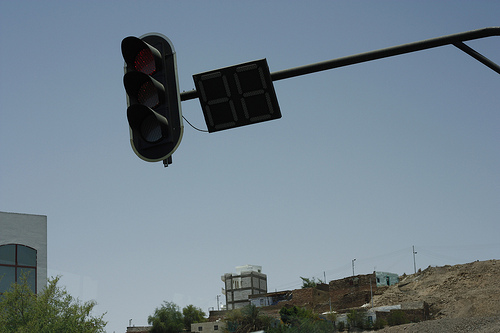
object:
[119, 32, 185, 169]
cones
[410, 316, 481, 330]
dirt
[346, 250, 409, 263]
power line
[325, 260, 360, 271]
power line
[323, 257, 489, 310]
top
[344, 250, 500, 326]
incline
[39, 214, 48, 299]
corner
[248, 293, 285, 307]
part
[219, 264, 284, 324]
house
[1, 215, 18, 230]
side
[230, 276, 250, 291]
side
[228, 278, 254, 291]
wall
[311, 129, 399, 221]
sky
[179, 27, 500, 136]
pole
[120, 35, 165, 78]
traffic light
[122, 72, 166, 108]
traffic light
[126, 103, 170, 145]
traffic light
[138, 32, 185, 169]
panel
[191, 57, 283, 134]
panel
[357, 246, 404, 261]
utility line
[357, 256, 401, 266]
utility line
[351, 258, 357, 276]
pole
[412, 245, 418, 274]
pole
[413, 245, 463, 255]
utility line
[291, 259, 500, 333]
base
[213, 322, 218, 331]
window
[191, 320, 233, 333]
building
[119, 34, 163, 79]
light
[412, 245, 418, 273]
poles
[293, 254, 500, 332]
hill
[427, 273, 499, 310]
dirt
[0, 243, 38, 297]
window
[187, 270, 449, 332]
hillside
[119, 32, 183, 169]
light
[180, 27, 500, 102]
pole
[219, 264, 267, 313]
building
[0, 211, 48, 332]
bilding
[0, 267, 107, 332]
tree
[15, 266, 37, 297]
window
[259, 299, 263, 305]
window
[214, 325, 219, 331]
window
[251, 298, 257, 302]
window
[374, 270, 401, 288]
building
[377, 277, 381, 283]
window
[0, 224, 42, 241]
wall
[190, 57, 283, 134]
seconds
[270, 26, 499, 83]
pole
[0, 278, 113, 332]
leaves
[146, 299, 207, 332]
branches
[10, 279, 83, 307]
top